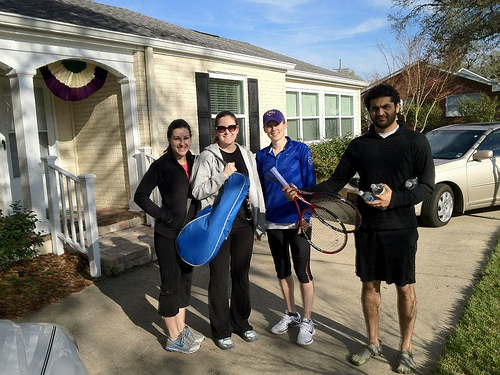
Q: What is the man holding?
A: Rackets.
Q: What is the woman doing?
A: Standing.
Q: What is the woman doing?
A: Standing.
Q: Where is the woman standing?
A: Driveway.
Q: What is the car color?
A: Gold.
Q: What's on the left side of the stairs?
A: White hand railing.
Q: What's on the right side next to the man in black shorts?
A: A patch of green grass.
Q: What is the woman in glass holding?
A: Blue tennis bag.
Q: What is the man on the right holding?
A: Two tennis rackets.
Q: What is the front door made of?
A: Wood.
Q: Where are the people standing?
A: A driveway of a house.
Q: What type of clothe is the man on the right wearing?
A: Long sleeved black shirt.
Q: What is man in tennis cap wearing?
A: Blue jacket.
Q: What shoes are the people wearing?
A: Sports shoes.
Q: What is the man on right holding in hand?
A: Two tennis rackets.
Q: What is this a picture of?
A: A group of tennis players.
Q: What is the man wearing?
A: A black outfit.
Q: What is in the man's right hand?
A: Tennis rackets.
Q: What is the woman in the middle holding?
A: A racket bag.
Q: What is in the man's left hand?
A: Beverages.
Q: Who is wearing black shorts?
A: The man.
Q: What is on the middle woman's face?
A: Sunglasses.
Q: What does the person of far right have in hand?
A: Racket.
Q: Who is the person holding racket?
A: Man.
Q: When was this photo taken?
A: Daytime.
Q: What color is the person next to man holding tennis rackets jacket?
A: Blue.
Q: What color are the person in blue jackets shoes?
A: White.